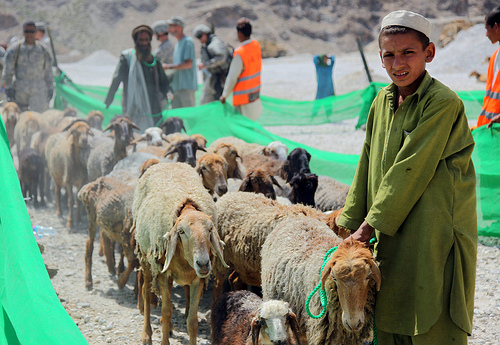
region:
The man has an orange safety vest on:
[228, 41, 268, 107]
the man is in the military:
[2, 21, 60, 106]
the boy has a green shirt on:
[333, 81, 482, 336]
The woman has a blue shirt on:
[308, 49, 343, 96]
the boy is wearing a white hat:
[376, 8, 446, 43]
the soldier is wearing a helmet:
[192, 21, 212, 35]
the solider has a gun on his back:
[41, 20, 73, 87]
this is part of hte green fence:
[252, 89, 369, 124]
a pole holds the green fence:
[351, 37, 373, 82]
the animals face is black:
[290, 148, 315, 178]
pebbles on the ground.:
[93, 312, 107, 327]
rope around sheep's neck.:
[310, 253, 331, 318]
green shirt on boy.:
[397, 211, 438, 281]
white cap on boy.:
[382, 13, 427, 23]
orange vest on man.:
[245, 47, 260, 67]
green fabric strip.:
[290, 98, 342, 119]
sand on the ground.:
[277, 60, 303, 95]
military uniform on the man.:
[22, 59, 37, 86]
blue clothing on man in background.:
[317, 72, 330, 96]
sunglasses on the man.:
[21, 28, 38, 36]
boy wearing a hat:
[367, 8, 477, 90]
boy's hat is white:
[367, 2, 472, 59]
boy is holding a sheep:
[326, 188, 412, 281]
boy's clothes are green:
[347, 95, 494, 332]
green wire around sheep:
[313, 230, 340, 315]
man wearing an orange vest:
[226, 39, 286, 126]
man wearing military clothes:
[5, 45, 75, 120]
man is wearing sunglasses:
[18, 15, 36, 42]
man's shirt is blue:
[166, 35, 208, 100]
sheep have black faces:
[281, 139, 323, 212]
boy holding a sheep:
[327, 5, 482, 343]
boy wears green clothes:
[330, 3, 485, 340]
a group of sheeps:
[8, 95, 368, 337]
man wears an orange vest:
[217, 19, 271, 116]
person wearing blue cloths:
[310, 45, 342, 102]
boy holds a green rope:
[296, 0, 483, 344]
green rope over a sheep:
[301, 226, 387, 342]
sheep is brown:
[128, 156, 228, 343]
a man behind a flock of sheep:
[94, 20, 188, 150]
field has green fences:
[0, 56, 496, 342]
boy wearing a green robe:
[362, 10, 490, 335]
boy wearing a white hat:
[372, 0, 447, 138]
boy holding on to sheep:
[323, 8, 498, 339]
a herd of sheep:
[110, 160, 390, 334]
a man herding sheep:
[105, 25, 175, 138]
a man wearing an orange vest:
[221, 9, 280, 122]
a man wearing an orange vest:
[475, 7, 497, 133]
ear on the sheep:
[210, 219, 231, 270]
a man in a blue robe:
[308, 35, 341, 114]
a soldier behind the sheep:
[9, 20, 61, 115]